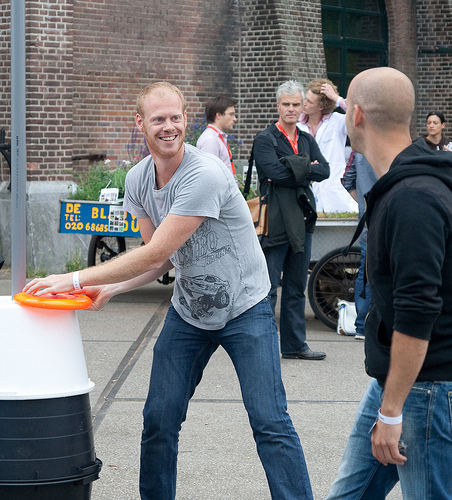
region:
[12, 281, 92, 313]
The orange frisbee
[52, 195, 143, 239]
The blue sign with the yellow writing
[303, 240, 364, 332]
The wheel to the silver cart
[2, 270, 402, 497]
The grey walkway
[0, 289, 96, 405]
The white plastic tub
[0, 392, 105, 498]
The black plastic tubs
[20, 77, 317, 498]
The man with the grey shirt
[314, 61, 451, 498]
The bald man in the black sweatshirt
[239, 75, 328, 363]
The man with the brown bag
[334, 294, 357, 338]
White bag on the ground near silver cart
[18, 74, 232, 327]
man gripping an orange Frisbee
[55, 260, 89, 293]
band around man's left wrist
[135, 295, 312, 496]
man wearing blue jeans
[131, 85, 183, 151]
man smiling broadly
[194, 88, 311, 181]
men wearing red lanyards around their necks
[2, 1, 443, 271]
brick and concrete building behind assembled people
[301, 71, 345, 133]
person holding hand to their head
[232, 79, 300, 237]
messenger bag hanging from man's right shoulder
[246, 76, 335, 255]
man holding a black jacket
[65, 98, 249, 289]
flowering plants on wheeled cart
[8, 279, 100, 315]
an orange frisbee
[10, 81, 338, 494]
a young man holding a frisbee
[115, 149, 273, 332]
a grey printed t-shirt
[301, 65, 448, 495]
a bald man walking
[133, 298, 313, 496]
a pair of blue jeans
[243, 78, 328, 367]
a man wearing a black suit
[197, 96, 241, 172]
a man standing in the background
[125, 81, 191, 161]
a smiling face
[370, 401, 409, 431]
a plastic wrist band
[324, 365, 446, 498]
a pair of blue jeans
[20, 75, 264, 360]
A man holding an orange frisbee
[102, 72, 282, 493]
A man in a gray shirt and blue jeans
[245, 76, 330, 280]
A gray haired man holding a black jacket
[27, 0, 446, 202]
A brick building behind people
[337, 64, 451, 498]
A man in a black hoodie and blue jeans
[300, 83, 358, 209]
A person wearing white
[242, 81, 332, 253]
A man with a brown messenger bag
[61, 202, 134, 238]
A sign with a telephone number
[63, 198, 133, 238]
A blue and yellow sign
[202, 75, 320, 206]
Two men with orange lanyards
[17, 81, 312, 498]
a smiling man holding a frisbee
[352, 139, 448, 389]
a black hoodie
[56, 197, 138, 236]
a blue and yellow sign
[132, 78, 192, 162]
a man's face with a short beard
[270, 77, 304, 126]
a man with grey hair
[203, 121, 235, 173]
a red lanyard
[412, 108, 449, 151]
a woman with black hair standing in the background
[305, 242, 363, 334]
a black tire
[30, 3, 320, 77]
a weathered brick wall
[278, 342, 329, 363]
a black shoe